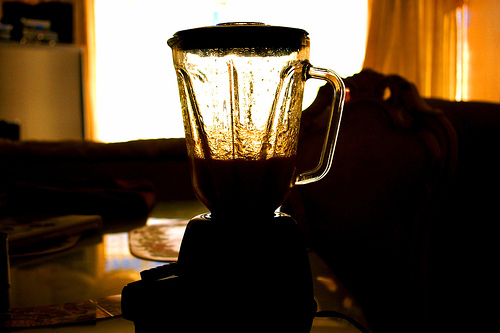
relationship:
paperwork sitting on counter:
[28, 290, 131, 323] [17, 253, 126, 330]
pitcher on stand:
[168, 21, 346, 220] [116, 213, 324, 326]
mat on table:
[128, 221, 190, 263] [4, 189, 380, 329]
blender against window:
[115, 19, 350, 330] [94, 3, 368, 139]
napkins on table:
[76, 192, 211, 304] [6, 212, 245, 331]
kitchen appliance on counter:
[165, 5, 350, 287] [0, 194, 500, 333]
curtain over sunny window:
[361, 0, 500, 101] [93, 2, 461, 144]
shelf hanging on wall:
[12, 9, 82, 59] [4, 0, 102, 150]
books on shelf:
[0, 0, 75, 46] [12, 9, 82, 59]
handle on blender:
[300, 69, 352, 191] [115, 19, 350, 330]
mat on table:
[128, 221, 190, 263] [84, 233, 409, 331]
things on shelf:
[5, 17, 69, 44] [7, 40, 87, 50]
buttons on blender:
[139, 261, 176, 280] [91, 27, 422, 275]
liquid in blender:
[189, 154, 296, 213] [142, 19, 372, 264]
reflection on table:
[100, 215, 180, 258] [5, 200, 360, 331]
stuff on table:
[127, 218, 196, 260] [5, 200, 360, 331]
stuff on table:
[91, 291, 123, 320] [5, 200, 360, 331]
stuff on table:
[3, 297, 96, 331] [5, 200, 360, 331]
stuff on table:
[10, 210, 100, 252] [5, 200, 360, 331]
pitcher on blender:
[168, 21, 346, 220] [115, 19, 350, 330]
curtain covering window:
[361, 0, 500, 101] [444, 0, 475, 100]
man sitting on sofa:
[301, 65, 463, 277] [300, 99, 498, 331]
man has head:
[301, 65, 463, 277] [346, 66, 388, 116]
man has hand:
[301, 65, 463, 277] [377, 72, 388, 88]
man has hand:
[301, 65, 463, 277] [340, 75, 351, 95]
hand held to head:
[377, 72, 388, 88] [346, 66, 388, 116]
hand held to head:
[340, 75, 351, 95] [346, 66, 388, 116]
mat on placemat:
[128, 221, 190, 263] [126, 220, 188, 264]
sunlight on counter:
[1, 2, 499, 330] [38, 74, 499, 289]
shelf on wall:
[0, 43, 86, 140] [0, 1, 84, 140]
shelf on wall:
[0, 0, 82, 48] [0, 1, 84, 140]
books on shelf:
[3, 8, 73, 45] [0, 0, 82, 48]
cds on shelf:
[0, 0, 74, 44] [0, 0, 82, 48]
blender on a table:
[115, 19, 350, 330] [5, 200, 360, 331]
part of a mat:
[129, 220, 186, 261] [119, 232, 176, 260]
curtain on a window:
[361, 0, 476, 101] [94, 3, 368, 139]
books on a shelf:
[0, 0, 75, 46] [2, 2, 79, 54]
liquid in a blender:
[189, 147, 296, 208] [115, 19, 350, 330]